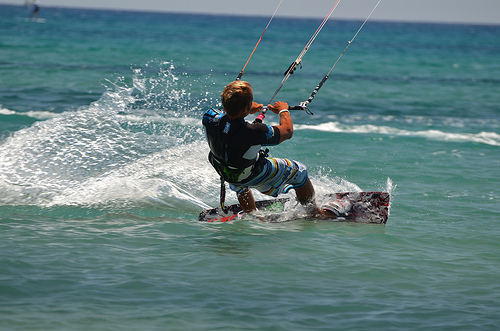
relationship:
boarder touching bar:
[200, 82, 317, 214] [228, 102, 315, 112]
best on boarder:
[208, 119, 247, 178] [200, 82, 317, 214]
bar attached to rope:
[228, 102, 315, 112] [266, 2, 339, 106]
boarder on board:
[200, 82, 317, 214] [197, 192, 390, 227]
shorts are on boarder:
[232, 156, 308, 198] [200, 82, 317, 214]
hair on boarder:
[221, 80, 253, 114] [200, 82, 317, 214]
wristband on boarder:
[279, 106, 292, 114] [200, 82, 317, 214]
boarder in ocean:
[200, 82, 317, 214] [3, 225, 500, 329]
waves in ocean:
[0, 108, 500, 151] [3, 225, 500, 329]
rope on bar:
[266, 2, 339, 106] [228, 102, 315, 112]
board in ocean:
[197, 192, 390, 227] [3, 225, 500, 329]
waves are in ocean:
[0, 108, 500, 151] [3, 225, 500, 329]